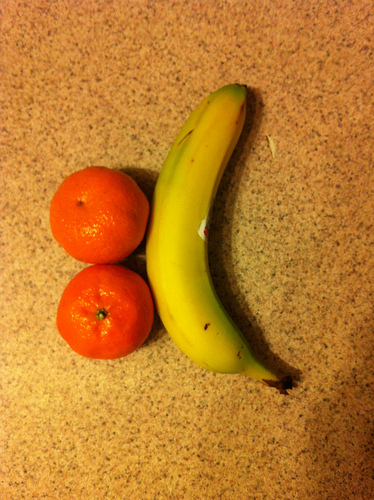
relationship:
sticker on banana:
[197, 211, 211, 243] [147, 78, 304, 395]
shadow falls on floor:
[204, 87, 300, 384] [0, 0, 372, 498]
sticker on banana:
[197, 211, 211, 243] [131, 68, 316, 398]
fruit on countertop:
[144, 82, 293, 402] [1, 1, 372, 498]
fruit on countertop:
[44, 160, 149, 263] [1, 1, 372, 498]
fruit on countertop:
[50, 262, 153, 361] [1, 1, 372, 498]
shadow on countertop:
[296, 347, 370, 498] [1, 1, 372, 498]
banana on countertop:
[142, 0, 297, 324] [1, 1, 372, 498]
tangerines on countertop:
[47, 165, 152, 360] [1, 1, 372, 498]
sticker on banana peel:
[191, 214, 216, 252] [195, 151, 212, 201]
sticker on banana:
[194, 211, 210, 238] [154, 84, 272, 402]